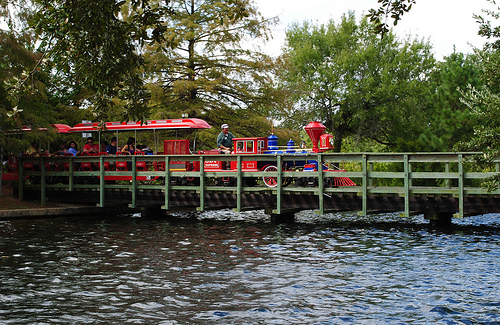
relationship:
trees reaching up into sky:
[273, 13, 451, 173] [254, 0, 482, 71]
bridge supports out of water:
[96, 186, 484, 230] [0, 205, 500, 322]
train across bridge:
[0, 117, 357, 188] [120, 146, 500, 231]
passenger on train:
[115, 137, 135, 156] [5, 117, 357, 200]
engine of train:
[260, 136, 317, 176] [0, 115, 365, 196]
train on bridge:
[0, 115, 365, 196] [0, 147, 499, 221]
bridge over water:
[0, 147, 499, 221] [0, 205, 500, 322]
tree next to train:
[96, 0, 302, 146] [0, 115, 365, 196]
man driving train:
[214, 121, 240, 170] [0, 115, 365, 196]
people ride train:
[44, 133, 151, 165] [2, 120, 360, 191]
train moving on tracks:
[0, 117, 357, 188] [71, 167, 484, 217]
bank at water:
[0, 192, 97, 219] [0, 205, 500, 322]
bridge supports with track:
[420, 202, 455, 227] [18, 145, 484, 208]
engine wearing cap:
[196, 122, 316, 189] [218, 120, 230, 130]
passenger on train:
[115, 136, 143, 156] [10, 115, 361, 188]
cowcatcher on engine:
[304, 113, 344, 155] [227, 134, 310, 190]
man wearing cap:
[214, 121, 240, 156] [218, 123, 230, 130]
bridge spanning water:
[229, 144, 373, 217] [171, 243, 271, 309]